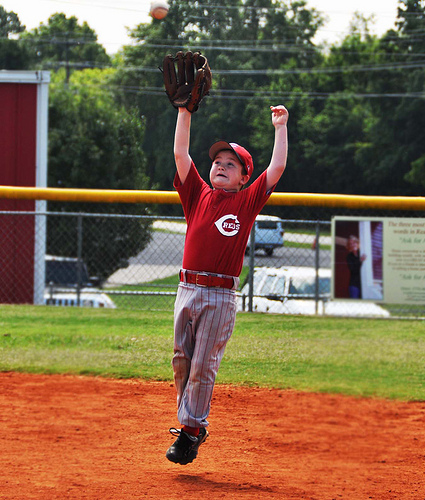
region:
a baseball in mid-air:
[146, 1, 170, 21]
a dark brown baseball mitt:
[159, 47, 214, 113]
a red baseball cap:
[206, 137, 256, 176]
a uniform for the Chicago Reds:
[162, 159, 277, 468]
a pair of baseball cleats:
[163, 423, 210, 467]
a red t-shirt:
[172, 160, 278, 278]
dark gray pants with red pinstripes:
[171, 267, 240, 429]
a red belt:
[176, 266, 240, 292]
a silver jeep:
[43, 253, 117, 311]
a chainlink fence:
[1, 211, 424, 319]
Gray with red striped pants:
[167, 258, 239, 428]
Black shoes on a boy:
[155, 422, 210, 462]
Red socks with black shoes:
[164, 417, 211, 463]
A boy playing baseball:
[147, 47, 276, 425]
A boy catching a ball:
[135, 0, 276, 360]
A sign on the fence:
[323, 211, 423, 313]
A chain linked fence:
[88, 208, 132, 293]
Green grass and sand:
[34, 336, 84, 411]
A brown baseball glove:
[155, 44, 217, 116]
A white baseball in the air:
[144, 3, 179, 24]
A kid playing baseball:
[145, 86, 255, 456]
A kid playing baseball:
[170, 173, 297, 483]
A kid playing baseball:
[213, 173, 284, 423]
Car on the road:
[245, 213, 284, 255]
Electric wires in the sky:
[6, 1, 423, 101]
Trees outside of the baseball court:
[0, 3, 422, 278]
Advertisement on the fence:
[330, 215, 424, 303]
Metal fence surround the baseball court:
[4, 210, 329, 312]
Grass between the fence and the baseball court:
[3, 303, 423, 398]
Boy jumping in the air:
[158, 48, 287, 463]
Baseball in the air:
[149, 0, 171, 18]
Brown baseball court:
[2, 369, 423, 498]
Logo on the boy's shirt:
[214, 212, 241, 236]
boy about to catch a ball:
[135, 6, 267, 474]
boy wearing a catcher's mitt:
[159, 49, 222, 116]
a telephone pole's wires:
[99, 30, 424, 99]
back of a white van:
[247, 213, 288, 253]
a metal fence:
[20, 210, 165, 305]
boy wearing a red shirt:
[181, 166, 263, 275]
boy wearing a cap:
[209, 131, 256, 174]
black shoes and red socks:
[163, 421, 223, 472]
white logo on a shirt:
[210, 202, 247, 245]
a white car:
[246, 262, 380, 319]